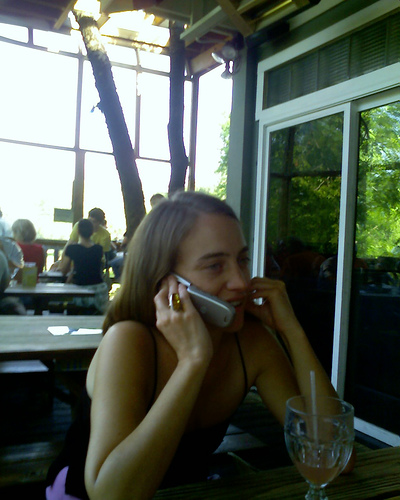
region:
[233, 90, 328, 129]
white frame on window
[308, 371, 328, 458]
white straw in glass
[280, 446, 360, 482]
yellow liquid in glass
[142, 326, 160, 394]
spaghetti straps on black shirt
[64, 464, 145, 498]
woman's elbow on table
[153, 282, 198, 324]
large gold ring on hand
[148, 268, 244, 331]
woman talking on silver phone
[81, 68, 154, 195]
tall black tree trunk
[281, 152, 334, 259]
clear glass in door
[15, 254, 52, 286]
yellow container with white top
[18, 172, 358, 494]
people dining in a restaurant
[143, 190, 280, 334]
girl talking on cellphone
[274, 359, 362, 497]
glass cup with a white straw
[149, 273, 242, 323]
silver flip cell phone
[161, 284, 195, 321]
ring on girl's right hand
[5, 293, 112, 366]
long brown wooden tables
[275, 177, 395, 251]
reflection of trees seen in windows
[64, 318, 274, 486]
girl wearing a black tank top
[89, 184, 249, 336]
gorl with long straight brown hair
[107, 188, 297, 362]
girl holding cell phone to her ear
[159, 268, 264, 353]
The woman talking on the cellphone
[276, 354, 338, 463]
A straw in the glass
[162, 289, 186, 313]
A yellow stone ring on her finger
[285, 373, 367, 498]
The glass on the table.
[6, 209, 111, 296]
People sittig at the table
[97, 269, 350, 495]
A lady sitting at the table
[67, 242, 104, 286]
The person is wearing a black shirt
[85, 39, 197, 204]
A tree trunk in the building.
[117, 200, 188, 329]
The girl has long brown hair.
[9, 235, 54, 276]
A person is wearing a red shirt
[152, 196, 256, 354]
a woman talking on a cell phone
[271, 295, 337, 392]
an arm of a person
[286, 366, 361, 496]
a straw in a glass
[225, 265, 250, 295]
the nose of a person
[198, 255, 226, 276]
an eye of a person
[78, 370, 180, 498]
a bent arm of a person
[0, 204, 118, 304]
people sitting at a table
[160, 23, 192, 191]
a trunk of a tree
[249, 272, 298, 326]
a hand of a person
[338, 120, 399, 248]
the reflection of leaves in a window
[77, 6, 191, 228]
two tree trunks in roof hole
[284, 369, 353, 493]
plastic straw in grass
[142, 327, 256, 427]
two black straps of shirt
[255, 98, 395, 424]
sliding glass doors on building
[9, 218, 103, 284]
people sitting at table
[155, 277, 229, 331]
hand on flip phone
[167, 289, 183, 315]
ring on woman's finger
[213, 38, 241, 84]
three lights below ceiling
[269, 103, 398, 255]
reflection of trees on glass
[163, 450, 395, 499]
grain on wood table